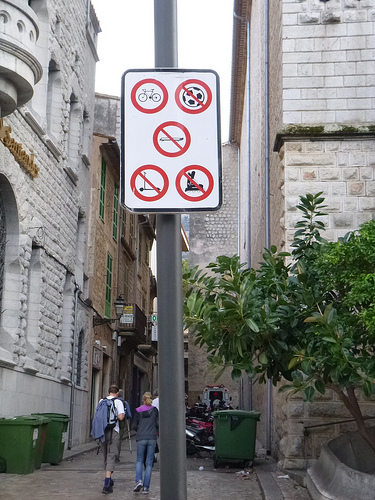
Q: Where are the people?
A: In alley.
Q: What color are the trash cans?
A: Green.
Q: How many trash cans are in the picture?
A: 3.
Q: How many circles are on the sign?
A: 5.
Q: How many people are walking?
A: Two.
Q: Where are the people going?
A: Down the street.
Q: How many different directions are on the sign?
A: Five.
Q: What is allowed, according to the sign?
A: Bicycles.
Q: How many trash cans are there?
A: Three.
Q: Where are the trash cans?
A: Along the side of the street.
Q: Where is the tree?
A: In a planter.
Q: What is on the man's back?
A: Backpack.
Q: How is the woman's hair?
A: In a ponytail.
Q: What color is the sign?
A: Red, black and white.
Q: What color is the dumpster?
A: Green.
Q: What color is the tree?
A: Green.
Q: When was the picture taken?
A: Daytime.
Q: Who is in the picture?
A: A man and a woman.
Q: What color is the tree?
A: Green.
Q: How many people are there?
A: Two.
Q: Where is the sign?
A: On the pole.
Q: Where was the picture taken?
A: In an alley.